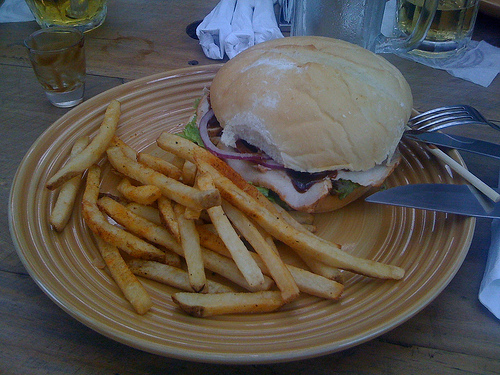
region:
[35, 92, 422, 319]
french fries on a plate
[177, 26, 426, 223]
ham, letuce, and onion sandwich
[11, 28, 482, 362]
meal for a person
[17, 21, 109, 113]
untouched drink next to meal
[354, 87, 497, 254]
various fork and knives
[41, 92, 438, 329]
well-seasoned golden french fries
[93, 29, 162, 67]
stain leftover from a glass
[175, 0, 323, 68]
silverware rolled up in napkins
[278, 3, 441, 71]
part of a water pitchure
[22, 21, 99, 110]
glass filled with a drink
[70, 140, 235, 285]
the pile of fries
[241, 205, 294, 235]
the seasoning on the fries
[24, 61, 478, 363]
the light brown plate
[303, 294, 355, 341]
the lines on the plate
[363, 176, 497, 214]
the knife resting on the plate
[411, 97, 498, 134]
the fork resting on the plate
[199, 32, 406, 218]
the whole burger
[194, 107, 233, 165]
the red onion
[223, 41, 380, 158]
the top bun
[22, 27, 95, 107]
the small cup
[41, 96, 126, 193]
a yellow fry on the plate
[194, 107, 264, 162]
a purple onion ring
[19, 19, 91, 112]
a small shot glass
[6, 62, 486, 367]
a brown porcelain plate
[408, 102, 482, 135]
the metal tines of a fork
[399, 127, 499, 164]
the blade of a knife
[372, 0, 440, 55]
the handle of a glass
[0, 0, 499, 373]
a brown wooden table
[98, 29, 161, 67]
a ring of moisture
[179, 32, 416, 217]
a sandwich on the plate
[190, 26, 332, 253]
a burger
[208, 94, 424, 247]
a burger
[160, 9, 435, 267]
a burger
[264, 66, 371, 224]
a burger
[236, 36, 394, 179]
a burger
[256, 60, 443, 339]
a burger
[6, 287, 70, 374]
brown wooden table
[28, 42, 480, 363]
dinner on a tan plate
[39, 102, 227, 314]
french fries on a tan plate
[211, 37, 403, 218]
hamburger on a tan plate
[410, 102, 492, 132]
silver fork leaning on plate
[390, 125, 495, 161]
silver kitchen knife leaning on plate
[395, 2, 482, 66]
pitcher of beer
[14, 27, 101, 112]
small empty shot glass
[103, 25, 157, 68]
water ring on table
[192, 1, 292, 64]
white napkins